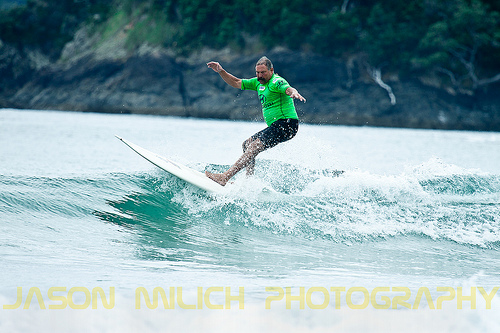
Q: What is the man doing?
A: Surfing.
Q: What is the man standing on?
A: Surfboard.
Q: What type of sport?
A: Surfing.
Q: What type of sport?
A: Surfing.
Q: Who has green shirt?
A: The man.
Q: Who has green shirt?
A: The man.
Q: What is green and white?
A: Water.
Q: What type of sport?
A: Surfing.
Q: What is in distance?
A: Hill.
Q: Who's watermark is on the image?
A: The photographer's name.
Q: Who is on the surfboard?
A: A surfer.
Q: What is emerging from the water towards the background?
A: Mountains.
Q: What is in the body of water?
A: A wave.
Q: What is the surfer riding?
A: A wave.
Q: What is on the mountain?
A: Shrubs.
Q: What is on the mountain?
A: An exposed rock.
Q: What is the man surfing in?
A: The ocean.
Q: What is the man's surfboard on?
A: The ocean.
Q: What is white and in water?
A: Surfboard.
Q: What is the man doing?
A: Surfer.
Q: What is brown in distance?
A: Boulders.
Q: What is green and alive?
A: Bushes.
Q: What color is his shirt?
A: Green.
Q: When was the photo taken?
A: Daytime.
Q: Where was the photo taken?
A: At the beach.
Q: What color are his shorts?
A: Black.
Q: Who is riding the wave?
A: Surfer.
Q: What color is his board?
A: White.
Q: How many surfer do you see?
A: One.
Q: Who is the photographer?
A: Jason Milich Photography.